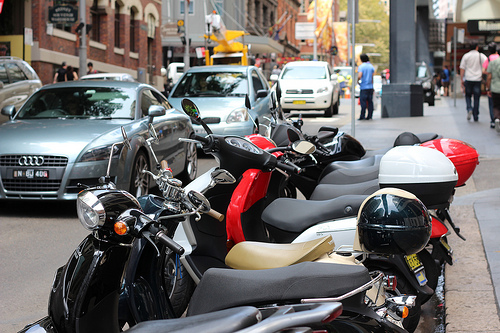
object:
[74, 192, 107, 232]
headlight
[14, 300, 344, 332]
scooters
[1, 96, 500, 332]
road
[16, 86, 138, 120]
windshield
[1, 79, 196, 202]
car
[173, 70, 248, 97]
windshield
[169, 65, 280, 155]
car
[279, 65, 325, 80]
windshield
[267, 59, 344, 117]
car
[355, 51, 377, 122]
man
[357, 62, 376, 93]
shirt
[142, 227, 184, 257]
handlebars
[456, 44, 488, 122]
people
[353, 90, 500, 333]
sidewalk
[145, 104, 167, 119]
sidemirror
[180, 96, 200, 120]
sidemirror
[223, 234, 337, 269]
seat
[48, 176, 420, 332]
scooter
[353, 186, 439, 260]
motorcycle helmet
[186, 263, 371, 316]
seat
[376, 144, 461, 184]
case lid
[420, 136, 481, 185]
case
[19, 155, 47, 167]
logo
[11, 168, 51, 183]
license plate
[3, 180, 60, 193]
grills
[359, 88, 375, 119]
jeans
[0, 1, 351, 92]
buildings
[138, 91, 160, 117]
window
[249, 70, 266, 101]
window